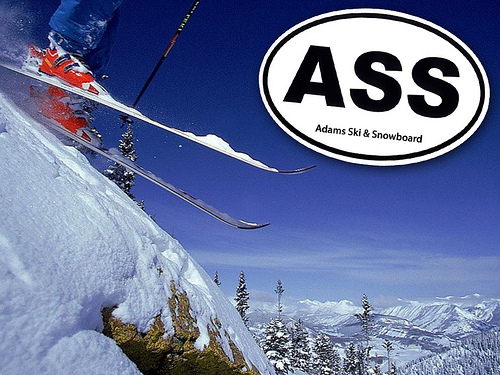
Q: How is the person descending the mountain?
A: Skiing.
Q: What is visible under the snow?
A: Rock.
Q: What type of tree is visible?
A: Pine.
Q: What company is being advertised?
A: Adams Ski & Snowboard.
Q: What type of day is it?
A: Sunny and clear.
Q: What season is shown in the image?
A: Winter.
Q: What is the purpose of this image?
A: Advertising.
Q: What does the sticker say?
A: ASS Adams Ski & Snowboard.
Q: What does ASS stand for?
A: Adams Ski & Snowboard.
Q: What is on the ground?
A: Snow.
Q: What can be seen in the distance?
A: Mountains.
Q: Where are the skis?
A: In the air.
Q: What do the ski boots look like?
A: Orange with black straps.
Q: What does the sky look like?
A: Blue with few clouds.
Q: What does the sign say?
A: Ass.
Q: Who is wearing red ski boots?
A: The skier.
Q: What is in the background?
A: Snow-covered mountains.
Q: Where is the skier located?
A: Jumping over a rock ledge.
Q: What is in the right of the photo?
A: An advertisement.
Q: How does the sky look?
A: Blue and clear.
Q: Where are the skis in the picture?
A: In mid-air.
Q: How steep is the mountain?
A: Very steep.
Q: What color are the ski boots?
A: Red.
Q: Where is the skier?
A: Top left.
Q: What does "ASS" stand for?
A: Adams Ski & Snowboard.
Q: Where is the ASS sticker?
A: Top right.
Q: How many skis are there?
A: Two.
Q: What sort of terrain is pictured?
A: Mountains.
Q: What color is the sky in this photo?
A: Blue.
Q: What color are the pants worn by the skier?
A: Blue.